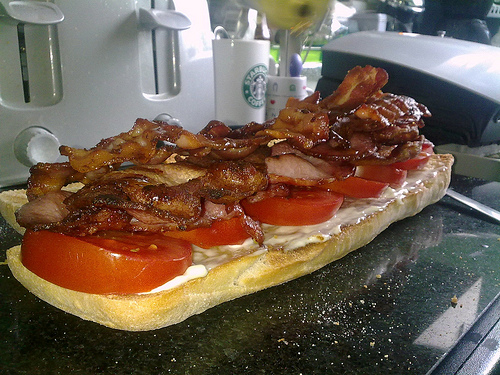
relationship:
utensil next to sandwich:
[447, 187, 481, 212] [53, 122, 339, 308]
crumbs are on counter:
[154, 267, 496, 374] [246, 224, 499, 373]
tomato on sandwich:
[17, 220, 193, 298] [10, 65, 471, 340]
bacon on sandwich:
[12, 60, 434, 240] [10, 65, 471, 340]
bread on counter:
[1, 153, 452, 336] [7, 202, 495, 374]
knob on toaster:
[11, 125, 61, 171] [1, 0, 216, 186]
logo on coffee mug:
[227, 67, 285, 119] [210, 38, 268, 127]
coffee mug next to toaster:
[210, 38, 268, 127] [5, 6, 210, 140]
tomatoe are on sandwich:
[18, 228, 194, 297] [10, 65, 471, 340]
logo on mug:
[243, 66, 267, 109] [207, 35, 272, 127]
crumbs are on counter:
[154, 267, 496, 374] [228, 256, 489, 372]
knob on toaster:
[13, 125, 61, 167] [1, 0, 216, 186]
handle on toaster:
[141, 3, 192, 31] [1, 0, 215, 188]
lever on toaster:
[8, 4, 65, 26] [1, 0, 215, 188]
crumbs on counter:
[371, 267, 412, 305] [402, 235, 492, 291]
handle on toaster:
[141, 3, 192, 42] [1, 0, 216, 186]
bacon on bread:
[14, 65, 431, 236] [1, 153, 452, 336]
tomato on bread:
[19, 142, 452, 295] [1, 153, 452, 336]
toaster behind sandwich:
[1, 0, 216, 186] [10, 65, 471, 340]